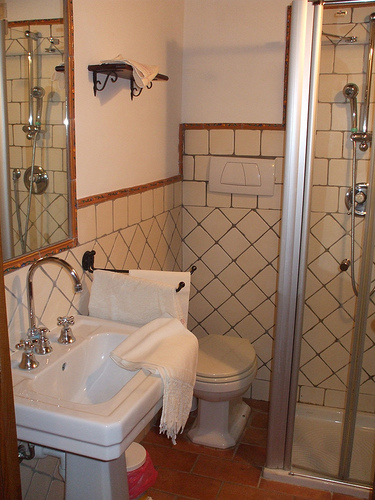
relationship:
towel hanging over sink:
[112, 311, 199, 445] [9, 312, 163, 499]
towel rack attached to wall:
[81, 246, 197, 294] [1, 0, 184, 500]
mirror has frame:
[0, 0, 70, 263] [0, 2, 79, 275]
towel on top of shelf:
[101, 53, 159, 90] [86, 62, 169, 102]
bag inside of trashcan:
[127, 452, 158, 499] [124, 442, 151, 499]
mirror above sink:
[0, 0, 70, 263] [9, 312, 163, 499]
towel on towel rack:
[88, 271, 184, 330] [81, 246, 197, 294]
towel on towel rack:
[130, 267, 191, 332] [81, 246, 197, 294]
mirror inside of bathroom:
[0, 0, 70, 263] [0, 0, 372, 497]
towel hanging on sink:
[112, 311, 199, 445] [9, 312, 163, 499]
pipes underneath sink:
[20, 442, 66, 481] [9, 312, 163, 499]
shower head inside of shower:
[341, 83, 362, 142] [263, 0, 373, 500]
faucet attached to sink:
[25, 256, 83, 336] [9, 312, 163, 499]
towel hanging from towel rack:
[88, 271, 184, 330] [81, 246, 197, 294]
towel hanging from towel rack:
[130, 267, 191, 332] [81, 246, 197, 294]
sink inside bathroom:
[9, 312, 163, 499] [0, 0, 372, 497]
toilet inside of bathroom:
[187, 332, 259, 450] [0, 0, 372, 497]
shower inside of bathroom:
[263, 0, 373, 500] [0, 0, 372, 497]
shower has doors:
[263, 0, 373, 500] [293, 3, 372, 491]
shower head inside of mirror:
[27, 86, 46, 138] [0, 0, 70, 263]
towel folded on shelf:
[101, 53, 159, 90] [86, 62, 169, 102]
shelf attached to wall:
[86, 62, 169, 102] [1, 0, 184, 500]